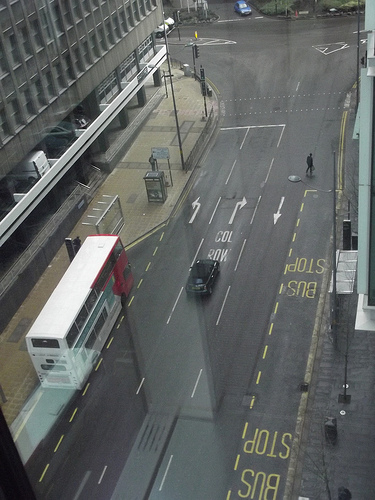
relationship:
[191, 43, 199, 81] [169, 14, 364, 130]
stoplight at corner of intersection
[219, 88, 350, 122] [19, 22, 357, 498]
crosswalk on a street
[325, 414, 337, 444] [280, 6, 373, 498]
garbage can on sidewalk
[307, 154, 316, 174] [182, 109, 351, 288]
pedestrian crossing street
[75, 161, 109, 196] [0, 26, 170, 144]
stairway entrance into building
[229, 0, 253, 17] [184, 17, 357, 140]
car waiting at intersection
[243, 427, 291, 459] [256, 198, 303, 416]
word on road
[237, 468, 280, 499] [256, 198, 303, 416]
word on road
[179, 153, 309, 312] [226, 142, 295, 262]
lines on road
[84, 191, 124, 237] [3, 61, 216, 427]
bus stop on sidewalk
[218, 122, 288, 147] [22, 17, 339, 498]
marking on road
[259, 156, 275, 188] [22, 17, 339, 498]
marking on road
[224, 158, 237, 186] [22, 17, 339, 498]
lines on road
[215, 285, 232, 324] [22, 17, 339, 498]
markings on road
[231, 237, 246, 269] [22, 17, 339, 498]
markings on road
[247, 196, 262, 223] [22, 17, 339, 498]
markings on road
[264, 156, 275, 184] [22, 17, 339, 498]
marking on road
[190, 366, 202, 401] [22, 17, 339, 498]
markings on road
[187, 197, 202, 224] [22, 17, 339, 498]
arrow on road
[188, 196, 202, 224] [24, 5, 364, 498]
arrow on road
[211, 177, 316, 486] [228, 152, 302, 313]
lines on road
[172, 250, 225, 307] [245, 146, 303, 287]
car on road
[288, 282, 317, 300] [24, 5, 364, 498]
word on road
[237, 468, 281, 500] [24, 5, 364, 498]
word on road